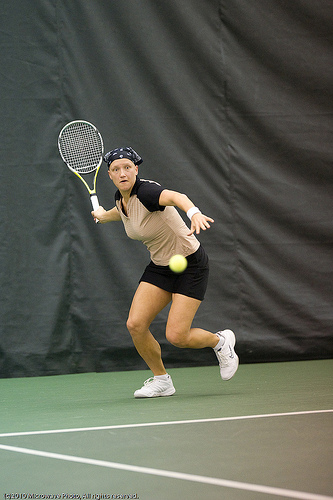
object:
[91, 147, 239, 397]
girl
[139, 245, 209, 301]
shorts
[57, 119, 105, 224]
racket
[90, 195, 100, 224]
handle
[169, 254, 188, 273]
ball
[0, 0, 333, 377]
tarp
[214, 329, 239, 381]
shoe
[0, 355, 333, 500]
ground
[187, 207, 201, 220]
wrist band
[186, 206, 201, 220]
wrist